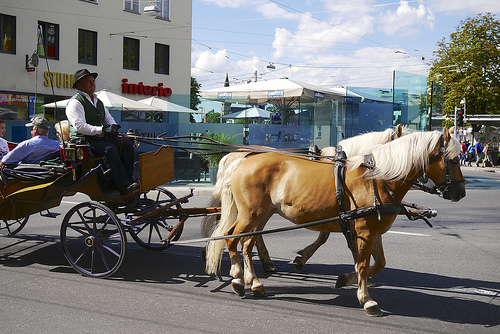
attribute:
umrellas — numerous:
[220, 66, 382, 133]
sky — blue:
[190, 0, 499, 91]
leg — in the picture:
[350, 235, 365, 298]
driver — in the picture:
[65, 68, 138, 193]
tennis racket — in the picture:
[196, 122, 468, 319]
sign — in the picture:
[110, 63, 182, 125]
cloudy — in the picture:
[274, 6, 439, 61]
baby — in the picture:
[120, 32, 146, 74]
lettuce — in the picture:
[150, 37, 175, 81]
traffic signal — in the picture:
[456, 110, 463, 129]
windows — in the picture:
[119, 35, 171, 75]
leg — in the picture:
[222, 187, 248, 298]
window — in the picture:
[2, 13, 20, 53]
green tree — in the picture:
[422, 9, 497, 116]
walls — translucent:
[0, 69, 420, 182]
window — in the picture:
[116, 21, 156, 81]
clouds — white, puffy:
[196, 3, 498, 88]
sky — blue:
[194, 5, 496, 109]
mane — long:
[347, 128, 464, 180]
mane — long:
[332, 121, 413, 156]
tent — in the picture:
[206, 69, 368, 128]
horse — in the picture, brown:
[208, 115, 469, 320]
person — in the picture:
[53, 45, 165, 222]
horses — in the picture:
[197, 109, 472, 321]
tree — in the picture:
[427, 7, 497, 142]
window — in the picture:
[152, 39, 179, 81]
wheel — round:
[60, 194, 132, 291]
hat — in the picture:
[23, 112, 53, 135]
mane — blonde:
[329, 119, 440, 186]